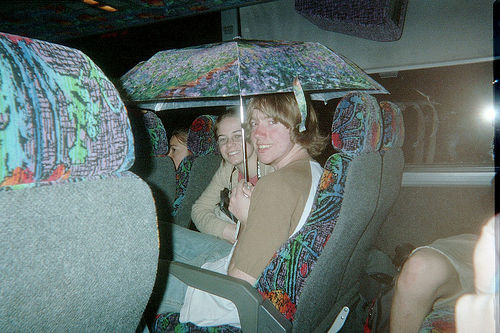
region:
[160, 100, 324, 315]
a couple sitting together on a bus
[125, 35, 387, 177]
an open umbrella on the bus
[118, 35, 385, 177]
the floral patterned umbrella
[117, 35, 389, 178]
an umbrella that matches the seats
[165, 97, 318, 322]
guy in white and brown t-shirt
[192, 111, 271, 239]
girl with glasses holding the umbrella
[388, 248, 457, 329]
the leg of the person sitting behind the couple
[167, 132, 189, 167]
head of girl sitting in front of couple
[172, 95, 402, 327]
the couple's two gray seats with colorful pattern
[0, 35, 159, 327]
back of seat across the aisle from couple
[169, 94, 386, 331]
two people sitting in bus seats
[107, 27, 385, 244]
an umbrella open inside the bus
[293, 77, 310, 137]
strap hanging down from the umbrella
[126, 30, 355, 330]
two people under the umbrella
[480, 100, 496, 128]
light glare on the window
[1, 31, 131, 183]
fabric on the back of the seat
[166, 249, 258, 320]
armrest is down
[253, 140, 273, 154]
smile on the face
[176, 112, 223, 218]
seat is slightly leaning back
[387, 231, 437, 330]
knee is bent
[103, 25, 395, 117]
floral print umbrella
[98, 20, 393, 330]
person holding open umbrella inside of bus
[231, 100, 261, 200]
metall handle of umbrella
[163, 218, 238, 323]
pair of light wash jeans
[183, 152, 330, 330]
tan and white short sleeve shirt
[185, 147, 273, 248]
tan long sleeve sweater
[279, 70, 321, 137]
closure for umbrella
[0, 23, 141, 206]
back of headrest on cushion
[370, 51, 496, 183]
window on side of bus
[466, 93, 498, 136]
round white flash reflected in window of bus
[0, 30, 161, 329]
large seat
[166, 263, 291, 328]
arm rest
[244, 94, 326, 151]
boy with sandy blonde hair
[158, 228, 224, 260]
blue jeans for leg wear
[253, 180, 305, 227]
brown and white shirt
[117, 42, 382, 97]
umbrella opened on bus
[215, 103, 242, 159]
girl with glasses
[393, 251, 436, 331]
hair leg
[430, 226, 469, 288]
cargo khaki shorts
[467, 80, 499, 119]
flash of camera